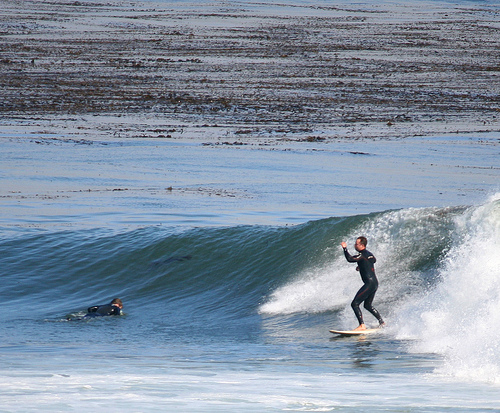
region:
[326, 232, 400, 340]
surfer on a board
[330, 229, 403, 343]
adult white male surfer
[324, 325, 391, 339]
white board in the water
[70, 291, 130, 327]
rescue dummy in the water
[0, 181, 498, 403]
large cresting ocean wave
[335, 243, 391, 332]
men's black wet suit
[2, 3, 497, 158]
mass of seaweed in distance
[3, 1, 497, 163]
seaweed floating on the water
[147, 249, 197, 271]
seaweed in the cresting wave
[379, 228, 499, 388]
splash created by surfer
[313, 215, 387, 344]
male surfer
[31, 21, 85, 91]
white clouds in blue sky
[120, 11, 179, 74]
white clouds in blue sky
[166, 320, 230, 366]
white and blue ocean waves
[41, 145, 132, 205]
white and blue ocean waves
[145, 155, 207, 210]
white and blue ocean waves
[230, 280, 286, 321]
white and blue ocean waves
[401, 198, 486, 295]
white and blue ocean waves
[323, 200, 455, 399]
Person in the water.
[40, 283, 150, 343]
Dog in the water.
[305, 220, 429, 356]
Man in a wet suit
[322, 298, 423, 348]
Surfboard in the water.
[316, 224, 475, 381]
Man who is surfing.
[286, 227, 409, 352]
Man in a black wetsuit.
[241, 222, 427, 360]
White spray in the ocean.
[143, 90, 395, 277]
Blue water in the ocean.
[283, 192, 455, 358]
Wave in the ocean.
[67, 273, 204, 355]
Dark dog in the water.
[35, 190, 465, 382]
two men in the ocean surfing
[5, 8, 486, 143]
ocean filled with seaweed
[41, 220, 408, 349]
two men wearing black wet suits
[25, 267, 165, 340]
man laying down on surfboard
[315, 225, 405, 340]
man standing on surfboard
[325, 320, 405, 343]
white surfboard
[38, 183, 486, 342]
large wave in the ocean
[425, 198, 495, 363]
white foam caused by crashing wave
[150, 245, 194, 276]
seaweed floating in water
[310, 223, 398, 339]
man's arms up to create balance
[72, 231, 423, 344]
two people surfing in the ocean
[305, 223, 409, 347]
man standing on white surfboard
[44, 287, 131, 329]
man laying down on surfboard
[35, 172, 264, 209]
sea weed on ocean surface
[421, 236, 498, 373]
white foam of crashing wave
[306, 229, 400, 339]
surfer with arms up for balance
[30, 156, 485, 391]
photograph taken at the ocean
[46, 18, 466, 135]
ocean covered with seaweed